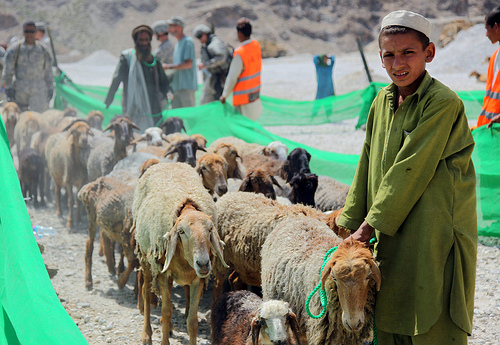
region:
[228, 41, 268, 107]
The man has an orange safety vest on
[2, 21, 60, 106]
the man is in the military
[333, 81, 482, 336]
the boy has a green shirt on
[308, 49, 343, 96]
The woman has a blue shirt on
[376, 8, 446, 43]
the boy is wearing a white hat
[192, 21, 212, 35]
the soldier is wearing a helmet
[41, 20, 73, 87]
the solider has a gun on his back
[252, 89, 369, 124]
this is part of hte green fence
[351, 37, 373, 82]
a pole holds the green fence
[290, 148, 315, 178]
the animals face is black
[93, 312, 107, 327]
pebbles on the ground.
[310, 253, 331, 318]
rope around sheep's neck.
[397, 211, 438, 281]
green shirt on boy.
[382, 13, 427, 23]
white cap on boy.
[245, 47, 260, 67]
orange vest on man.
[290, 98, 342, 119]
green fabric strip.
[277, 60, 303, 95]
sand on the ground.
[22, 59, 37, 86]
military uniform on the man.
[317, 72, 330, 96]
blue clothing on man in background.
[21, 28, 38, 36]
sunglasses on the man.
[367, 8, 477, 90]
boy wearing a hat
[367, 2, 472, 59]
boy's hat is white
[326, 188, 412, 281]
boy is holding a sheep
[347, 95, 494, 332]
boy's clothes are green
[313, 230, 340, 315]
green wire around sheep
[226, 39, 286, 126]
man wearing an orange vest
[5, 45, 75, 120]
man wearing military clothes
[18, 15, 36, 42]
man is wearing sunglasses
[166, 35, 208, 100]
man's shirt is blue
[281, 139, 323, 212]
sheep have black faces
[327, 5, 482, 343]
boy holding a sheep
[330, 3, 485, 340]
boy wears green clothes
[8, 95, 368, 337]
a group of sheeps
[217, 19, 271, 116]
man wears an orange vest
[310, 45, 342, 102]
person wearing blue cloths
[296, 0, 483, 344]
boy holds a green rope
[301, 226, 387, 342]
green rope over a sheep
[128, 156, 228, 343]
sheep is brown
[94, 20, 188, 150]
a man behind a flock of sheep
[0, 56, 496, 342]
field has green fences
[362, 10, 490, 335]
boy wearing a green robe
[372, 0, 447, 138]
boy wearing a white hat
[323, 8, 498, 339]
boy holding on to sheep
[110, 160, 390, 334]
a herd of sheep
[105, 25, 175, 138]
a man herding sheep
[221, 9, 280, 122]
a man wearing an orange vest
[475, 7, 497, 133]
a man wearing an orange vest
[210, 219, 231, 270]
ear on the sheep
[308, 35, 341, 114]
a man in a blue robe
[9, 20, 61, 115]
a soldier behind the sheep